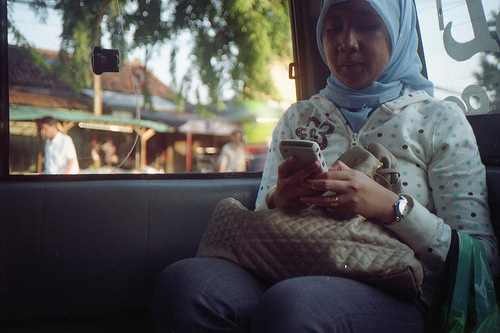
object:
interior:
[7, 177, 268, 331]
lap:
[214, 228, 438, 301]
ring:
[330, 195, 339, 208]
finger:
[305, 179, 350, 192]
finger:
[300, 194, 347, 206]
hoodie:
[255, 88, 499, 283]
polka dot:
[418, 129, 423, 133]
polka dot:
[441, 146, 447, 150]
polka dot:
[390, 134, 396, 138]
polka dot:
[423, 114, 430, 119]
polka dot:
[455, 143, 460, 148]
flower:
[295, 117, 335, 151]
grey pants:
[153, 258, 430, 332]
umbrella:
[224, 100, 284, 121]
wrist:
[377, 188, 422, 230]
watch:
[384, 194, 415, 226]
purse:
[196, 196, 426, 301]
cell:
[278, 140, 323, 171]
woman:
[147, 0, 498, 333]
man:
[41, 116, 80, 174]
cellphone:
[279, 139, 329, 177]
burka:
[315, 0, 433, 132]